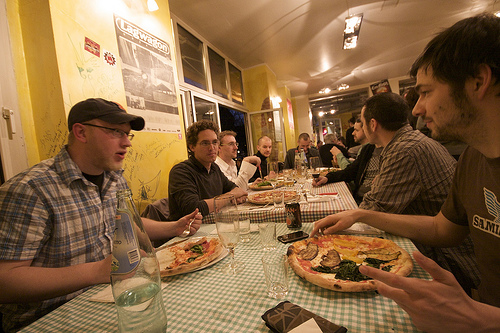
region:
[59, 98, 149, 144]
man wearing a green hat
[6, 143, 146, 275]
man wearing a plaid shirt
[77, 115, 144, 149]
man wearing black glasses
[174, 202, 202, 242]
man holding a fork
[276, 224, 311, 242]
cellphone on a table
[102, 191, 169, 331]
bottle of water on the table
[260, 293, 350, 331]
wallet on the table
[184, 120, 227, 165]
man with brown hair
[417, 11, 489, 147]
man with brown hair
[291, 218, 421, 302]
Pizza on the plate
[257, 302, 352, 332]
Brown designed wallet with a paper on it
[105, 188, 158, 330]
big half filled glass bottle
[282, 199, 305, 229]
Small soda drink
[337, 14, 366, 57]
Large light hanging on the ceiling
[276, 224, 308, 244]
Cell phone on a table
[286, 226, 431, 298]
A big whole pizza, with part of a hand and part of a cell phone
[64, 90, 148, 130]
A mans brown hat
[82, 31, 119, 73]
Two small red pictures on the wall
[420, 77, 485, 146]
A mans mustache and beard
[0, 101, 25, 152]
Knob on a window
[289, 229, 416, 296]
Pizza on the table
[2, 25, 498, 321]
People eating at tables at a restaurant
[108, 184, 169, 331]
Glass bottle on the table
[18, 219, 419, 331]
Green and white checkered tablecloths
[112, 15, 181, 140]
Poster on the wall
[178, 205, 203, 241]
Fork in man's left hand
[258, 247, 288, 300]
Empty glass on the table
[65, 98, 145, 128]
Cap on man's head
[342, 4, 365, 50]
Light hanging from ceiling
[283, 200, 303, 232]
Beverage can on the table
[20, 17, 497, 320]
these people are in a restaurant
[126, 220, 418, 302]
they are eating pizza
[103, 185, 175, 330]
a water bottle sits on the table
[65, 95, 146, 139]
the man is wearing a baseball hat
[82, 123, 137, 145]
the man wears glasses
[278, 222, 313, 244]
a cell phone sits on the table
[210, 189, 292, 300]
several empty glasses sit on the table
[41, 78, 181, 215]
some writing and drawings are on the wall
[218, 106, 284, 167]
the door for the establishment is open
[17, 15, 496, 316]
all the people sitting at these tables are men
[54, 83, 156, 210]
man is wearing eyeglasses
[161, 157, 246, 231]
the sweater is black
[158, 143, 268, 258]
the sweater is black